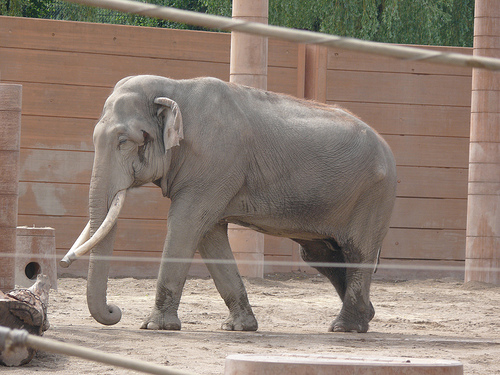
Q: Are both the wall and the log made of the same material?
A: Yes, both the wall and the log are made of wood.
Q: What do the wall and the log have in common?
A: The material, both the wall and the log are wooden.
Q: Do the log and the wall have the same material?
A: Yes, both the log and the wall are made of wood.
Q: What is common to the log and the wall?
A: The material, both the log and the wall are wooden.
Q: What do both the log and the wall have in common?
A: The material, both the log and the wall are wooden.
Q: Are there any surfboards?
A: No, there are no surfboards.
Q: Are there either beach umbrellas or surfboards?
A: No, there are no surfboards or beach umbrellas.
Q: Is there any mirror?
A: No, there are no mirrors.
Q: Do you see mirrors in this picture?
A: No, there are no mirrors.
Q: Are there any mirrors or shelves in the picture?
A: No, there are no mirrors or shelves.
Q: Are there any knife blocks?
A: No, there are no knife blocks.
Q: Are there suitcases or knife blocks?
A: No, there are no knife blocks or suitcases.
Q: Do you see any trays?
A: No, there are no trays.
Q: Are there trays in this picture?
A: No, there are no trays.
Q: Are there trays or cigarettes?
A: No, there are no trays or cigarettes.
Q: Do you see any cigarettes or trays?
A: No, there are no trays or cigarettes.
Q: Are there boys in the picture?
A: No, there are no boys.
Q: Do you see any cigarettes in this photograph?
A: No, there are no cigarettes.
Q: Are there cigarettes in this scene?
A: No, there are no cigarettes.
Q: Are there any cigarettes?
A: No, there are no cigarettes.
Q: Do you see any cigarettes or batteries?
A: No, there are no cigarettes or batteries.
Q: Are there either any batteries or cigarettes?
A: No, there are no cigarettes or batteries.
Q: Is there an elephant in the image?
A: Yes, there is an elephant.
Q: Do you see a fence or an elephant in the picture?
A: Yes, there is an elephant.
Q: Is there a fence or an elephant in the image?
A: Yes, there is an elephant.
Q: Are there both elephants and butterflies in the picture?
A: No, there is an elephant but no butterflies.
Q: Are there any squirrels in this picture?
A: No, there are no squirrels.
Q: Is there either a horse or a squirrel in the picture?
A: No, there are no squirrels or horses.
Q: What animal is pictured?
A: The animal is an elephant.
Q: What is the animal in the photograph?
A: The animal is an elephant.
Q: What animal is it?
A: The animal is an elephant.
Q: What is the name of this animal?
A: This is an elephant.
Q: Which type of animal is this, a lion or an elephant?
A: This is an elephant.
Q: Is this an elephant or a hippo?
A: This is an elephant.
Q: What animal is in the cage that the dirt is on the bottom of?
A: The elephant is in the cage.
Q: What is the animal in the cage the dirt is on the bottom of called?
A: The animal is an elephant.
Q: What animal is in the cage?
A: The animal is an elephant.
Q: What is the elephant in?
A: The elephant is in the cage.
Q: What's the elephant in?
A: The elephant is in the cage.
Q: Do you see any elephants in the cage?
A: Yes, there is an elephant in the cage.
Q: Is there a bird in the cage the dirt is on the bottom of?
A: No, there is an elephant in the cage.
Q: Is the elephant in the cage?
A: Yes, the elephant is in the cage.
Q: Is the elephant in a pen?
A: No, the elephant is in the cage.